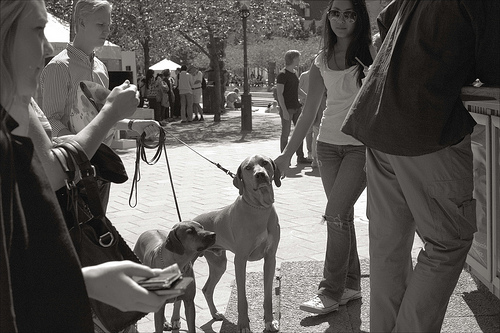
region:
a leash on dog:
[174, 132, 239, 181]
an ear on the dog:
[163, 227, 179, 253]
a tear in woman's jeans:
[321, 208, 351, 227]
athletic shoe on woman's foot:
[304, 300, 336, 318]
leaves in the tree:
[132, 1, 201, 36]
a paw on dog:
[235, 322, 246, 331]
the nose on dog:
[202, 229, 220, 245]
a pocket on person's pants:
[442, 195, 483, 247]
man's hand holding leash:
[134, 117, 177, 164]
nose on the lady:
[39, 43, 56, 58]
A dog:
[218, 147, 275, 265]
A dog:
[230, 127, 308, 322]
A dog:
[201, 65, 301, 313]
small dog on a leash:
[124, 212, 219, 330]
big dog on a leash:
[200, 146, 295, 331]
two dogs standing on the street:
[137, 148, 297, 331]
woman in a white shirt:
[263, 3, 400, 328]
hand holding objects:
[83, 239, 217, 324]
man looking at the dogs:
[40, 3, 122, 213]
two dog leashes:
[114, 112, 224, 213]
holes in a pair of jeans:
[318, 202, 355, 244]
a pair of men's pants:
[353, 121, 479, 331]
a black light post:
[236, 5, 268, 133]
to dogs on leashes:
[149, 131, 342, 330]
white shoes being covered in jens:
[301, 278, 366, 316]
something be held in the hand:
[115, 257, 222, 317]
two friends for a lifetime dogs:
[134, 161, 299, 312]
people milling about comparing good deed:
[32, 20, 486, 331]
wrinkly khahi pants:
[358, 140, 480, 331]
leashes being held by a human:
[127, 104, 207, 211]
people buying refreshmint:
[140, 35, 284, 116]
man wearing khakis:
[351, 119, 482, 325]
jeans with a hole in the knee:
[305, 127, 372, 308]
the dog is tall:
[213, 144, 292, 331]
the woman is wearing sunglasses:
[286, 3, 366, 319]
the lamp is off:
[231, 6, 258, 136]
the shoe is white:
[296, 285, 342, 325]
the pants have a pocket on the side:
[431, 180, 478, 252]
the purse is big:
[51, 146, 171, 321]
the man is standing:
[58, 4, 134, 126]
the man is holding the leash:
[58, 6, 168, 166]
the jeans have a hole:
[321, 211, 344, 228]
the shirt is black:
[270, 67, 300, 112]